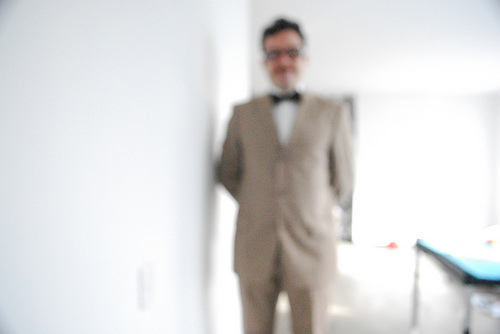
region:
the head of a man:
[244, 0, 332, 107]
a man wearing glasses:
[240, 15, 331, 111]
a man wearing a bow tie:
[227, 67, 343, 127]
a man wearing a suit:
[200, 55, 415, 305]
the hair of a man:
[240, 6, 325, 73]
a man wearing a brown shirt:
[195, 72, 476, 203]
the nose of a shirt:
[267, 43, 297, 70]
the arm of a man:
[210, 78, 286, 191]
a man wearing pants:
[222, 220, 423, 328]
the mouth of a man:
[261, 55, 321, 88]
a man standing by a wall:
[203, 9, 356, 329]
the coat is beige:
[204, 89, 356, 287]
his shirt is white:
[261, 93, 305, 145]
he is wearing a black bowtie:
[262, 89, 301, 106]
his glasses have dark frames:
[262, 44, 302, 59]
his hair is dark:
[254, 10, 308, 41]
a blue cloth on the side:
[405, 239, 495, 302]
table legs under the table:
[402, 244, 491, 330]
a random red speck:
[385, 232, 401, 251]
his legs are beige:
[225, 272, 335, 331]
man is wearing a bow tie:
[265, 80, 309, 103]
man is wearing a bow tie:
[252, 89, 327, 108]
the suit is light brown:
[198, 65, 410, 331]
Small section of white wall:
[5, 140, 41, 209]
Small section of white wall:
[3, 205, 42, 257]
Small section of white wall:
[7, 247, 41, 282]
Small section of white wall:
[15, 285, 75, 323]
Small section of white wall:
[87, 283, 149, 320]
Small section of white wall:
[147, 282, 225, 323]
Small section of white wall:
[140, 176, 255, 272]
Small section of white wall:
[124, 84, 195, 143]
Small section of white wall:
[135, 25, 173, 55]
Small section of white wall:
[51, 16, 95, 91]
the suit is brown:
[226, 108, 341, 332]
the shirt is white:
[281, 109, 293, 131]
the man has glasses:
[213, 39, 351, 314]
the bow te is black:
[268, 91, 309, 107]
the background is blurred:
[364, 83, 469, 177]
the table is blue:
[419, 234, 497, 299]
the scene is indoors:
[4, 31, 496, 331]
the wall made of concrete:
[110, 165, 165, 255]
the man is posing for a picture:
[221, 38, 351, 330]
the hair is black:
[262, 18, 307, 40]